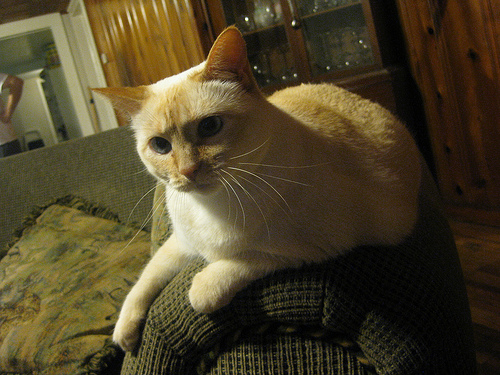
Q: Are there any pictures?
A: No, there are no pictures.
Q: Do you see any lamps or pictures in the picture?
A: No, there are no pictures or lamps.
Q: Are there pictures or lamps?
A: No, there are no pictures or lamps.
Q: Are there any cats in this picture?
A: Yes, there is a cat.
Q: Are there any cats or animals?
A: Yes, there is a cat.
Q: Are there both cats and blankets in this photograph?
A: No, there is a cat but no blankets.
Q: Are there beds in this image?
A: No, there are no beds.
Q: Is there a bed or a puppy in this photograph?
A: No, there are no beds or puppys.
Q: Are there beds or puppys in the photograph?
A: No, there are no beds or puppys.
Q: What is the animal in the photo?
A: The animal is a cat.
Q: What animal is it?
A: The animal is a cat.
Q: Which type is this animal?
A: This is a cat.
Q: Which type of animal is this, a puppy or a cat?
A: This is a cat.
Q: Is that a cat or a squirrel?
A: That is a cat.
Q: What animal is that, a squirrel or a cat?
A: That is a cat.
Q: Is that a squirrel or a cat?
A: That is a cat.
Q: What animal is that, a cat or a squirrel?
A: That is a cat.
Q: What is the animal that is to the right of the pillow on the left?
A: The animal is a cat.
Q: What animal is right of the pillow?
A: The animal is a cat.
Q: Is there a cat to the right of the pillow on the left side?
A: Yes, there is a cat to the right of the pillow.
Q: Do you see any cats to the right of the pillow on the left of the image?
A: Yes, there is a cat to the right of the pillow.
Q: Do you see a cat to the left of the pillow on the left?
A: No, the cat is to the right of the pillow.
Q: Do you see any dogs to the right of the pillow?
A: No, there is a cat to the right of the pillow.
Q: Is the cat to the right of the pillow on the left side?
A: Yes, the cat is to the right of the pillow.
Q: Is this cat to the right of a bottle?
A: No, the cat is to the right of the pillow.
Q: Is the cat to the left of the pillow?
A: No, the cat is to the right of the pillow.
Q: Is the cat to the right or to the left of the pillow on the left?
A: The cat is to the right of the pillow.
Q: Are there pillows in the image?
A: Yes, there is a pillow.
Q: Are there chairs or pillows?
A: Yes, there is a pillow.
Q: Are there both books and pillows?
A: No, there is a pillow but no books.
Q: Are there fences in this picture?
A: No, there are no fences.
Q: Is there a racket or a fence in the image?
A: No, there are no fences or rackets.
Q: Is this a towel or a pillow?
A: This is a pillow.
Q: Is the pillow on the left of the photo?
A: Yes, the pillow is on the left of the image.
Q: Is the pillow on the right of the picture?
A: No, the pillow is on the left of the image.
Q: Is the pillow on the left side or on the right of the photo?
A: The pillow is on the left of the image.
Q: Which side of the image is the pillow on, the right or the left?
A: The pillow is on the left of the image.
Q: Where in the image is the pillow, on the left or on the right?
A: The pillow is on the left of the image.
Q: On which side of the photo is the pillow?
A: The pillow is on the left of the image.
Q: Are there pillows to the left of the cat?
A: Yes, there is a pillow to the left of the cat.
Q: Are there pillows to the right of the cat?
A: No, the pillow is to the left of the cat.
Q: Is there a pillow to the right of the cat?
A: No, the pillow is to the left of the cat.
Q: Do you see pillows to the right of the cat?
A: No, the pillow is to the left of the cat.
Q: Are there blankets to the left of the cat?
A: No, there is a pillow to the left of the cat.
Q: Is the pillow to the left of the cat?
A: Yes, the pillow is to the left of the cat.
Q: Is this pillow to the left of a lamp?
A: No, the pillow is to the left of the cat.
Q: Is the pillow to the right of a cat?
A: No, the pillow is to the left of a cat.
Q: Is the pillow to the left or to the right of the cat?
A: The pillow is to the left of the cat.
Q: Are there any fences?
A: No, there are no fences.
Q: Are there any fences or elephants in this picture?
A: No, there are no fences or elephants.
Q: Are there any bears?
A: No, there are no bears.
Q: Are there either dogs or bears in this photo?
A: No, there are no bears or dogs.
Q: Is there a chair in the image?
A: Yes, there is a chair.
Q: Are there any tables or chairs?
A: Yes, there is a chair.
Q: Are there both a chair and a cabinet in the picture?
A: Yes, there are both a chair and a cabinet.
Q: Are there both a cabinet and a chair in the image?
A: Yes, there are both a chair and a cabinet.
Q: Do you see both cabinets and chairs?
A: Yes, there are both a chair and cabinets.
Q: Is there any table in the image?
A: No, there are no tables.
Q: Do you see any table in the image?
A: No, there are no tables.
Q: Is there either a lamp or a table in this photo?
A: No, there are no tables or lamps.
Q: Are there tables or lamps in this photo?
A: No, there are no tables or lamps.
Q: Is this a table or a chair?
A: This is a chair.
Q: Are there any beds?
A: No, there are no beds.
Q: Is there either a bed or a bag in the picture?
A: No, there are no beds or bags.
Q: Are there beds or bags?
A: No, there are no beds or bags.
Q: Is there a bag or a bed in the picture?
A: No, there are no beds or bags.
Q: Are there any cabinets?
A: Yes, there is a cabinet.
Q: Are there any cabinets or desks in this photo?
A: Yes, there is a cabinet.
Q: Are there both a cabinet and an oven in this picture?
A: No, there is a cabinet but no ovens.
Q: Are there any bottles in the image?
A: No, there are no bottles.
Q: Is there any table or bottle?
A: No, there are no bottles or tables.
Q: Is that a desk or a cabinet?
A: That is a cabinet.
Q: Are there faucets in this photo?
A: No, there are no faucets.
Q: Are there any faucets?
A: No, there are no faucets.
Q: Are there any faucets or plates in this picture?
A: No, there are no faucets or plates.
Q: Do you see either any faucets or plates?
A: No, there are no faucets or plates.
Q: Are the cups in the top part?
A: Yes, the cups are in the top of the image.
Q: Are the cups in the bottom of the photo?
A: No, the cups are in the top of the image.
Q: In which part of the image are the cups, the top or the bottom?
A: The cups are in the top of the image.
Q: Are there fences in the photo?
A: No, there are no fences.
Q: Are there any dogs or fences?
A: No, there are no fences or dogs.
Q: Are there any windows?
A: Yes, there is a window.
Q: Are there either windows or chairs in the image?
A: Yes, there is a window.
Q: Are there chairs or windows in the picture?
A: Yes, there is a window.